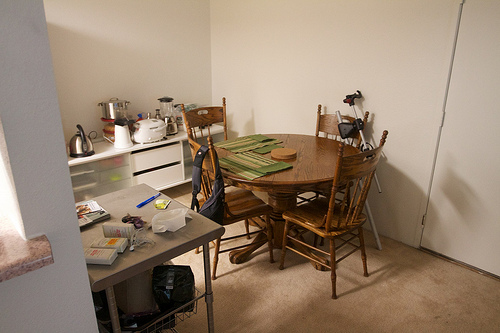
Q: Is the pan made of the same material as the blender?
A: Yes, both the pan and the blender are made of metal.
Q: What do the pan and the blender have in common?
A: The material, both the pan and the blender are metallic.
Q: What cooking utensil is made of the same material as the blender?
A: The pan is made of the same material as the blender.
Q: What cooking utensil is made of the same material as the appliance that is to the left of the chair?
A: The pan is made of the same material as the blender.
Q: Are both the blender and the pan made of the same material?
A: Yes, both the blender and the pan are made of metal.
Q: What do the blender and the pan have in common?
A: The material, both the blender and the pan are metallic.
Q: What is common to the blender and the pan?
A: The material, both the blender and the pan are metallic.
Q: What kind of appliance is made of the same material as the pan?
A: The blender is made of the same material as the pan.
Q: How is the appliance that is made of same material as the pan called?
A: The appliance is a blender.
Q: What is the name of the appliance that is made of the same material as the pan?
A: The appliance is a blender.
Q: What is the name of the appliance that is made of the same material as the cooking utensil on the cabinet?
A: The appliance is a blender.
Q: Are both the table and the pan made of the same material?
A: No, the table is made of wood and the pan is made of metal.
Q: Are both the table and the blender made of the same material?
A: No, the table is made of wood and the blender is made of metal.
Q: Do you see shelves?
A: No, there are no shelves.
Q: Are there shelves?
A: No, there are no shelves.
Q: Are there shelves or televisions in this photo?
A: No, there are no shelves or televisions.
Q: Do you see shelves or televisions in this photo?
A: No, there are no shelves or televisions.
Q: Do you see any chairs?
A: Yes, there is a chair.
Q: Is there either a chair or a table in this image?
A: Yes, there is a chair.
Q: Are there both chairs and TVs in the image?
A: No, there is a chair but no televisions.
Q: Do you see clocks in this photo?
A: No, there are no clocks.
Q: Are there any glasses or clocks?
A: No, there are no clocks or glasses.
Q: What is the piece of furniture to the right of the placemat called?
A: The piece of furniture is a chair.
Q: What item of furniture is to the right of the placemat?
A: The piece of furniture is a chair.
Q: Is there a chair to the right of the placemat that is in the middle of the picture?
A: Yes, there is a chair to the right of the placemat.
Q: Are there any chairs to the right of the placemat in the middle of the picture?
A: Yes, there is a chair to the right of the placemat.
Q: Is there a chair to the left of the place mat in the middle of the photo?
A: No, the chair is to the right of the placemat.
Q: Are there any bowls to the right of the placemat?
A: No, there is a chair to the right of the placemat.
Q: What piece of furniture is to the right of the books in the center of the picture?
A: The piece of furniture is a chair.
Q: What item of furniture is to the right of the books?
A: The piece of furniture is a chair.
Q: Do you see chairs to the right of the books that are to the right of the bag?
A: Yes, there is a chair to the right of the books.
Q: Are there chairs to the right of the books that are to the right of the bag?
A: Yes, there is a chair to the right of the books.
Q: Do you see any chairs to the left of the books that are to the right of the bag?
A: No, the chair is to the right of the books.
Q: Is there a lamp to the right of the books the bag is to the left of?
A: No, there is a chair to the right of the books.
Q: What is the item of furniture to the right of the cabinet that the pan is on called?
A: The piece of furniture is a chair.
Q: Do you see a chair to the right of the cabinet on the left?
A: Yes, there is a chair to the right of the cabinet.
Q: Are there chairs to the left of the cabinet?
A: No, the chair is to the right of the cabinet.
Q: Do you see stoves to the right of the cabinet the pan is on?
A: No, there is a chair to the right of the cabinet.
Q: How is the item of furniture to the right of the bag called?
A: The piece of furniture is a chair.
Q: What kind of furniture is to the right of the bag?
A: The piece of furniture is a chair.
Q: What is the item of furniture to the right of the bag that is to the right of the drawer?
A: The piece of furniture is a chair.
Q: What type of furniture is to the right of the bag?
A: The piece of furniture is a chair.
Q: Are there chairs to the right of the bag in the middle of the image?
A: Yes, there is a chair to the right of the bag.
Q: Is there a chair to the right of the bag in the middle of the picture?
A: Yes, there is a chair to the right of the bag.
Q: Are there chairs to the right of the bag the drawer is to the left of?
A: Yes, there is a chair to the right of the bag.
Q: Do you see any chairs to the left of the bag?
A: No, the chair is to the right of the bag.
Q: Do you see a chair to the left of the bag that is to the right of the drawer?
A: No, the chair is to the right of the bag.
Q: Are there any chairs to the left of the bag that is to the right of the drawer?
A: No, the chair is to the right of the bag.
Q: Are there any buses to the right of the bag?
A: No, there is a chair to the right of the bag.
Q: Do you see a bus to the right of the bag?
A: No, there is a chair to the right of the bag.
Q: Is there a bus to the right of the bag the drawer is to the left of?
A: No, there is a chair to the right of the bag.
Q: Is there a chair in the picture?
A: Yes, there is a chair.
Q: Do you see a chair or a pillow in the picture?
A: Yes, there is a chair.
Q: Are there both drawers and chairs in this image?
A: Yes, there are both a chair and a drawer.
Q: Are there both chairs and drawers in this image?
A: Yes, there are both a chair and a drawer.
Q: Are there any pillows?
A: No, there are no pillows.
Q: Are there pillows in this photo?
A: No, there are no pillows.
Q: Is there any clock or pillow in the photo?
A: No, there are no pillows or clocks.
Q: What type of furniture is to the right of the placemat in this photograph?
A: The piece of furniture is a chair.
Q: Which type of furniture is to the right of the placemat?
A: The piece of furniture is a chair.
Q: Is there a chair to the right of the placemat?
A: Yes, there is a chair to the right of the placemat.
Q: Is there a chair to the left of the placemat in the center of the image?
A: No, the chair is to the right of the placemat.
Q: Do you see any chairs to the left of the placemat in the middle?
A: No, the chair is to the right of the placemat.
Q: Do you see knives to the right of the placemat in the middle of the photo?
A: No, there is a chair to the right of the placemat.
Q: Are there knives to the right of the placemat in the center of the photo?
A: No, there is a chair to the right of the placemat.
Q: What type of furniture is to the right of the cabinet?
A: The piece of furniture is a chair.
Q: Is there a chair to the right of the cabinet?
A: Yes, there is a chair to the right of the cabinet.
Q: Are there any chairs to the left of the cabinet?
A: No, the chair is to the right of the cabinet.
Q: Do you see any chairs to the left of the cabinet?
A: No, the chair is to the right of the cabinet.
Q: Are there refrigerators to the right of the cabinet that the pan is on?
A: No, there is a chair to the right of the cabinet.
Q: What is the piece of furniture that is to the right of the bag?
A: The piece of furniture is a chair.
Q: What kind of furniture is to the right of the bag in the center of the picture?
A: The piece of furniture is a chair.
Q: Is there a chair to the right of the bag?
A: Yes, there is a chair to the right of the bag.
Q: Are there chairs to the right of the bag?
A: Yes, there is a chair to the right of the bag.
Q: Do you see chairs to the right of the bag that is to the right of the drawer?
A: Yes, there is a chair to the right of the bag.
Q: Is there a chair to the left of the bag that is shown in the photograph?
A: No, the chair is to the right of the bag.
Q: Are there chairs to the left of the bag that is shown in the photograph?
A: No, the chair is to the right of the bag.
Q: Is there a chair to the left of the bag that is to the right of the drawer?
A: No, the chair is to the right of the bag.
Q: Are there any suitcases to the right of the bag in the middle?
A: No, there is a chair to the right of the bag.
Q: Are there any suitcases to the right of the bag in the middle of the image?
A: No, there is a chair to the right of the bag.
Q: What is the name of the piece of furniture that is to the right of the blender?
A: The piece of furniture is a chair.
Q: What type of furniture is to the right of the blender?
A: The piece of furniture is a chair.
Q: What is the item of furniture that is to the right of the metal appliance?
A: The piece of furniture is a chair.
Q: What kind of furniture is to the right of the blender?
A: The piece of furniture is a chair.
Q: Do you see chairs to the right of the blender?
A: Yes, there is a chair to the right of the blender.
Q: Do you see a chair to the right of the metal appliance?
A: Yes, there is a chair to the right of the blender.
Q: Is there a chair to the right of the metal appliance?
A: Yes, there is a chair to the right of the blender.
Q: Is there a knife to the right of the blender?
A: No, there is a chair to the right of the blender.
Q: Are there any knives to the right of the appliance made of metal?
A: No, there is a chair to the right of the blender.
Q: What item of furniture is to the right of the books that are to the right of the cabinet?
A: The piece of furniture is a chair.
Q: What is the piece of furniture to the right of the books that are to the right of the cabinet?
A: The piece of furniture is a chair.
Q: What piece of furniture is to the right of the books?
A: The piece of furniture is a chair.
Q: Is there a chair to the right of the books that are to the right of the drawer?
A: Yes, there is a chair to the right of the books.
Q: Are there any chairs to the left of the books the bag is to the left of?
A: No, the chair is to the right of the books.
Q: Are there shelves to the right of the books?
A: No, there is a chair to the right of the books.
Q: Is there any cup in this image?
A: No, there are no cups.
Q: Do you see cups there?
A: No, there are no cups.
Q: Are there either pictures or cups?
A: No, there are no cups or pictures.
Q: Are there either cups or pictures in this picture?
A: No, there are no cups or pictures.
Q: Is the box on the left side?
A: Yes, the box is on the left of the image.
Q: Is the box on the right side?
A: No, the box is on the left of the image.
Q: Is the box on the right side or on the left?
A: The box is on the left of the image.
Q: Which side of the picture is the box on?
A: The box is on the left of the image.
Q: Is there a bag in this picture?
A: Yes, there is a bag.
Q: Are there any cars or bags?
A: Yes, there is a bag.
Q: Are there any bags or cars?
A: Yes, there is a bag.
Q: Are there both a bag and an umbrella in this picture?
A: No, there is a bag but no umbrellas.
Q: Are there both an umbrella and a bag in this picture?
A: No, there is a bag but no umbrellas.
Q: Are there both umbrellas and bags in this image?
A: No, there is a bag but no umbrellas.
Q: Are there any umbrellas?
A: No, there are no umbrellas.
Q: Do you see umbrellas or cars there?
A: No, there are no umbrellas or cars.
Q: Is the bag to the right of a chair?
A: No, the bag is to the left of a chair.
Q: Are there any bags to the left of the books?
A: Yes, there is a bag to the left of the books.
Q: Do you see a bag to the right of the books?
A: No, the bag is to the left of the books.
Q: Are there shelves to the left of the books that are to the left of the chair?
A: No, there is a bag to the left of the books.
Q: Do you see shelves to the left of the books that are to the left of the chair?
A: No, there is a bag to the left of the books.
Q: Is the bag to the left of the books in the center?
A: Yes, the bag is to the left of the books.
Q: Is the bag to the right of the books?
A: No, the bag is to the left of the books.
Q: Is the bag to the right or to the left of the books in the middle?
A: The bag is to the left of the books.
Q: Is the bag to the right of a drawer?
A: Yes, the bag is to the right of a drawer.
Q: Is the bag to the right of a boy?
A: No, the bag is to the right of a drawer.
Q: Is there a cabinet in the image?
A: Yes, there is a cabinet.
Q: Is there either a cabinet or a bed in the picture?
A: Yes, there is a cabinet.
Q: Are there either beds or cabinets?
A: Yes, there is a cabinet.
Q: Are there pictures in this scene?
A: No, there are no pictures.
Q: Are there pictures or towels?
A: No, there are no pictures or towels.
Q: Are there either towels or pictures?
A: No, there are no pictures or towels.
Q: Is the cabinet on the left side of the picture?
A: Yes, the cabinet is on the left of the image.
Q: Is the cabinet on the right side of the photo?
A: No, the cabinet is on the left of the image.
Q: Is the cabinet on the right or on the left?
A: The cabinet is on the left of the image.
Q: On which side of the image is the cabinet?
A: The cabinet is on the left of the image.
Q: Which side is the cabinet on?
A: The cabinet is on the left of the image.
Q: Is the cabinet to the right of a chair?
A: No, the cabinet is to the left of a chair.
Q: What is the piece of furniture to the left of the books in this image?
A: The piece of furniture is a cabinet.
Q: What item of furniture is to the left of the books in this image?
A: The piece of furniture is a cabinet.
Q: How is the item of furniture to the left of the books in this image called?
A: The piece of furniture is a cabinet.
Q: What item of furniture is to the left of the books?
A: The piece of furniture is a cabinet.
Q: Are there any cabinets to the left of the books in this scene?
A: Yes, there is a cabinet to the left of the books.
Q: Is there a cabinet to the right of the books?
A: No, the cabinet is to the left of the books.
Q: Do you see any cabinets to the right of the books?
A: No, the cabinet is to the left of the books.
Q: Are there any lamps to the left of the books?
A: No, there is a cabinet to the left of the books.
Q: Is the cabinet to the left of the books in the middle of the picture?
A: Yes, the cabinet is to the left of the books.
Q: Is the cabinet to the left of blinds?
A: No, the cabinet is to the left of the books.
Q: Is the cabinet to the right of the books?
A: No, the cabinet is to the left of the books.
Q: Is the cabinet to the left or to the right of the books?
A: The cabinet is to the left of the books.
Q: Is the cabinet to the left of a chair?
A: Yes, the cabinet is to the left of a chair.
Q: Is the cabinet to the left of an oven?
A: No, the cabinet is to the left of a chair.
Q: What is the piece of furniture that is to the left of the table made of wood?
A: The piece of furniture is a cabinet.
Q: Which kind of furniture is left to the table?
A: The piece of furniture is a cabinet.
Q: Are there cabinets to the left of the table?
A: Yes, there is a cabinet to the left of the table.